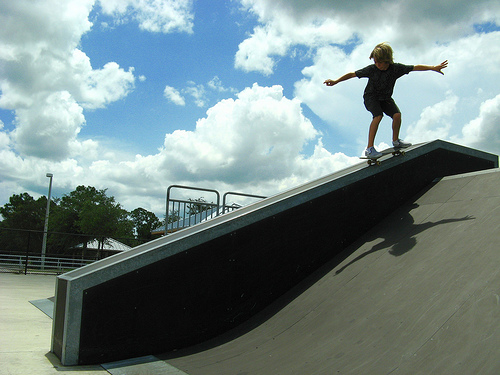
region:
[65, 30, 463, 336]
kid skateboarding down the ramp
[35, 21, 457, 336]
young person skateboarding down the ramp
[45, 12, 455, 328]
youth skateboarding down the ramp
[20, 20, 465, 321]
small kid skateboarding down ramp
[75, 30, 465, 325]
small person skateboarding down the ramp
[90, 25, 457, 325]
small youth skateboarding down the ramp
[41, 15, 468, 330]
kid riding skateboard down ramp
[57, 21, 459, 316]
young kid riding skateboard down ramp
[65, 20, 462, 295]
small person riding skateboard down ramp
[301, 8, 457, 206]
person riding high on skateboard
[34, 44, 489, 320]
picture taken outdoors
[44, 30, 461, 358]
picture taken during the day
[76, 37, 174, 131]
the sky is blue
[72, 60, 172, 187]
it is a sunny day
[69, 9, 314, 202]
puffy clouds in the sky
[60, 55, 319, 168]
the clouds are white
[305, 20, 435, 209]
a boy on a skateboard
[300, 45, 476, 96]
the boy's arms are out for balance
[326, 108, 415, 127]
the boy is wearing shorts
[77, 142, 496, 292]
the boy is skateboarding downhill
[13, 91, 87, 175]
a cloud in the sky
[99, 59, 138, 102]
a cloud in the sky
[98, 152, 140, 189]
a cloud in the sky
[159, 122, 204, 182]
a cloud in the sky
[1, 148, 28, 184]
a cloud in the sky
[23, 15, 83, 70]
a cloud in the sky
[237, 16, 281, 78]
a cloud in the sky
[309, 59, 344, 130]
a cloud in the sky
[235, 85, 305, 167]
a cloud in the sky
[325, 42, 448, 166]
young surfer in black shirt and shorts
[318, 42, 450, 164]
young boy skateboarding on top of wall barrier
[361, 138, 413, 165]
skateboard under the boy's feet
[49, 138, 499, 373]
concrete skating ramp with wall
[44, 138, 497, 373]
dark gray wall on ramp in skatepark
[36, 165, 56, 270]
light pole with lamp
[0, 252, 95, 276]
metal fence surrounding the skatepark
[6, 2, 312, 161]
smokey clouds in the sky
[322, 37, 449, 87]
boy's arms extended outward for balance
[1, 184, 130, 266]
trees with green leaves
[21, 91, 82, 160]
a cloud in the sky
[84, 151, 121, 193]
a cloud in the sky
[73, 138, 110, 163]
a cloud in the sky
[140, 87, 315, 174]
a cloud in the sky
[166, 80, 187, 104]
a cloud in the sky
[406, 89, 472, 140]
a cloud in the sky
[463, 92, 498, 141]
a cloud in the sky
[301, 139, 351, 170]
a cloud in the sky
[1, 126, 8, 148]
a cloud in the sky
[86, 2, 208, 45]
a cloud in the sky